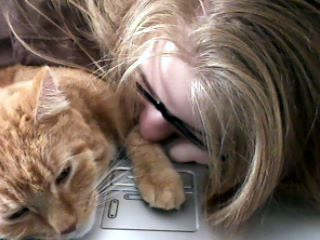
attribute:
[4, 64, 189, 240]
cat — orange, looking, adult, resting, large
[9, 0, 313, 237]
blonde hair — long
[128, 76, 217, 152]
glasses — black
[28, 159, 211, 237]
keyboard — silver